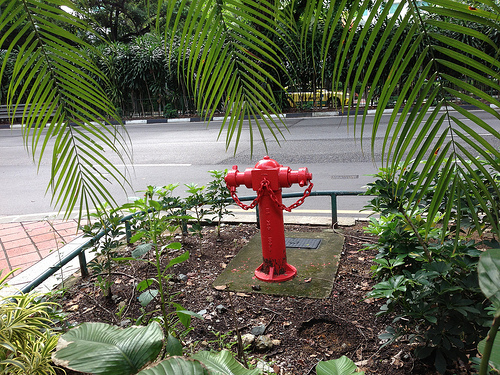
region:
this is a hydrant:
[224, 150, 307, 279]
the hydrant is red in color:
[223, 155, 313, 280]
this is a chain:
[274, 196, 314, 217]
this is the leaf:
[54, 315, 157, 373]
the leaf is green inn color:
[84, 332, 141, 367]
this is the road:
[157, 120, 216, 170]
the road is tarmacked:
[163, 120, 210, 179]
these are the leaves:
[350, 12, 473, 166]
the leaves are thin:
[360, 26, 447, 165]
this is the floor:
[301, 245, 333, 278]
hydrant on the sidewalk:
[216, 150, 330, 307]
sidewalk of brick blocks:
[6, 230, 81, 282]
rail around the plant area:
[13, 187, 471, 204]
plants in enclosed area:
[116, 218, 481, 371]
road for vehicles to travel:
[3, 132, 485, 184]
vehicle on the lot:
[281, 72, 361, 114]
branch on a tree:
[4, 10, 143, 204]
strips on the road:
[76, 145, 193, 176]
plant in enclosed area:
[3, 293, 57, 365]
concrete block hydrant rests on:
[231, 226, 334, 292]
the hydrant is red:
[220, 144, 320, 282]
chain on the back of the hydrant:
[217, 175, 316, 216]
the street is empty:
[89, 109, 371, 166]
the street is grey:
[104, 104, 354, 166]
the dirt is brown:
[257, 280, 369, 355]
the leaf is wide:
[53, 310, 161, 365]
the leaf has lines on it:
[35, 314, 161, 360]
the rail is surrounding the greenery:
[35, 200, 197, 295]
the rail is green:
[15, 197, 202, 294]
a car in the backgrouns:
[240, 67, 355, 115]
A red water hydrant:
[217, 150, 320, 289]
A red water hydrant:
[220, 145, 322, 290]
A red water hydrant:
[221, 150, 321, 292]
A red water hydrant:
[221, 149, 317, 286]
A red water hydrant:
[220, 149, 319, 299]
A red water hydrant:
[217, 152, 317, 293]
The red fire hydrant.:
[220, 155, 315, 285]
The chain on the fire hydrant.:
[227, 180, 315, 216]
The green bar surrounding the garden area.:
[1, 176, 426, 306]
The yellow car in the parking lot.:
[267, 76, 352, 108]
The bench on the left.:
[3, 100, 63, 126]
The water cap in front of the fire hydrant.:
[281, 233, 324, 250]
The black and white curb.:
[16, 100, 497, 125]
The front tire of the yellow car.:
[328, 97, 337, 107]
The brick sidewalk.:
[2, 218, 92, 267]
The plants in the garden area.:
[92, 171, 497, 372]